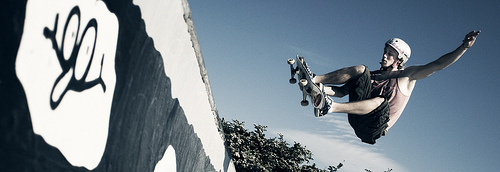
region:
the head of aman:
[367, 28, 460, 68]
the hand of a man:
[450, 22, 491, 68]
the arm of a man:
[392, 28, 494, 113]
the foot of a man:
[298, 83, 343, 143]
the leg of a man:
[311, 82, 422, 128]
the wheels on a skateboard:
[274, 47, 344, 122]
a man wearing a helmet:
[365, 28, 422, 73]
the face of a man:
[363, 22, 425, 68]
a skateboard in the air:
[281, 7, 386, 131]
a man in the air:
[296, 13, 476, 155]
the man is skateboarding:
[270, 12, 471, 150]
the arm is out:
[301, 5, 491, 155]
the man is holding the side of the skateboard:
[263, 31, 383, 153]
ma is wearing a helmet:
[340, 14, 425, 83]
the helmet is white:
[361, 20, 423, 79]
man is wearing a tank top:
[357, 37, 414, 143]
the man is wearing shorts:
[324, 45, 401, 152]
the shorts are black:
[317, 47, 394, 157]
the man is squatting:
[289, 21, 431, 151]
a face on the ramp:
[3, 2, 139, 124]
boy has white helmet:
[378, 34, 419, 76]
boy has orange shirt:
[351, 80, 409, 144]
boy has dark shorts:
[325, 47, 407, 142]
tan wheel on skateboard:
[295, 51, 337, 113]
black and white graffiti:
[38, 3, 220, 170]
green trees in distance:
[204, 120, 352, 170]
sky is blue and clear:
[188, 0, 269, 78]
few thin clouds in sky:
[260, 107, 351, 168]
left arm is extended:
[365, 18, 487, 106]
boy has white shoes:
[310, 71, 354, 138]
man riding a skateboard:
[273, 23, 488, 145]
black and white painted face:
[3, 10, 133, 170]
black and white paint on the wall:
[5, 5, 145, 167]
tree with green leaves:
[209, 113, 348, 168]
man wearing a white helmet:
[372, 31, 413, 72]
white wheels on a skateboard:
[284, 53, 322, 114]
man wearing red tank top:
[278, 25, 488, 142]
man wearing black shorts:
[279, 20, 486, 147]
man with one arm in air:
[277, 25, 484, 153]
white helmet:
[377, 32, 413, 75]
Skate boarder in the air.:
[278, 16, 484, 147]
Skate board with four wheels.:
[282, 55, 329, 113]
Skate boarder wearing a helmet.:
[380, 40, 412, 67]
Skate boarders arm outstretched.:
[404, 16, 481, 89]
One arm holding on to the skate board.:
[287, 54, 379, 114]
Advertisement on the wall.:
[15, 0, 132, 168]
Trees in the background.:
[215, 110, 392, 170]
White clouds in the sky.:
[239, 92, 418, 169]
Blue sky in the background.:
[191, 0, 498, 167]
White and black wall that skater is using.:
[0, 0, 242, 170]